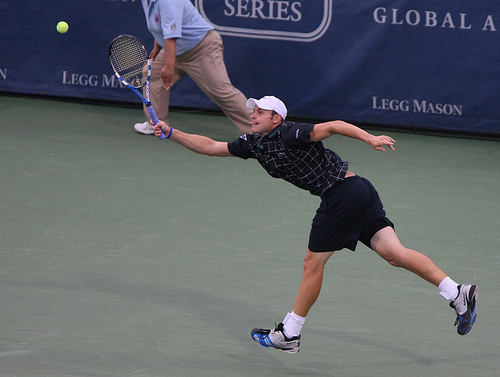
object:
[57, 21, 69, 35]
tennis ball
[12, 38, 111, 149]
air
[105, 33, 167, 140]
racket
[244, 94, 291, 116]
cap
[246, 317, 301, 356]
feet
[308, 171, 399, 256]
shorts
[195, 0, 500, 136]
wall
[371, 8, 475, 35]
word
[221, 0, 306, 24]
word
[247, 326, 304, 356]
left shoe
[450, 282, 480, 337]
right shoe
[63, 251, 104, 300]
part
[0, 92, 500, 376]
court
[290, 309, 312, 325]
edge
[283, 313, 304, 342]
sock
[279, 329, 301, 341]
edge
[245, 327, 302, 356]
shoe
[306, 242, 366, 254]
edge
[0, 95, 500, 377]
floor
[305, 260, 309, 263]
part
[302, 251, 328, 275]
knee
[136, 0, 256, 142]
person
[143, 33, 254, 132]
pants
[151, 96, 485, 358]
person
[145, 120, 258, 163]
right arm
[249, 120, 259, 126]
tongue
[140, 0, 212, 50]
shirt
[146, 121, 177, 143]
hand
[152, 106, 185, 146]
front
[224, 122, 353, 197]
shirt